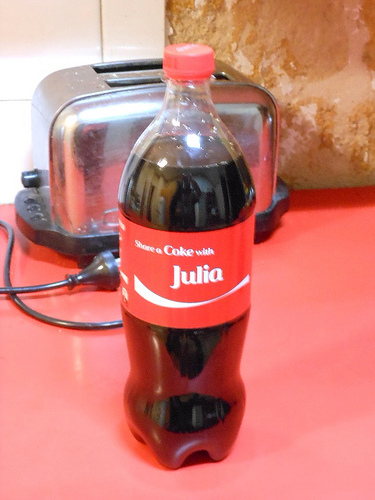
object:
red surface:
[0, 195, 375, 497]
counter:
[2, 191, 374, 497]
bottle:
[116, 44, 255, 469]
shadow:
[288, 188, 373, 209]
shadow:
[246, 332, 371, 452]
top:
[162, 41, 214, 84]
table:
[0, 193, 373, 500]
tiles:
[0, 0, 100, 100]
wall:
[0, 1, 374, 207]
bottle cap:
[162, 42, 215, 78]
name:
[169, 264, 223, 289]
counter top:
[0, 186, 375, 500]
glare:
[187, 133, 200, 149]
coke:
[116, 41, 256, 472]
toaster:
[21, 55, 278, 236]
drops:
[177, 144, 183, 150]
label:
[118, 212, 255, 331]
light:
[187, 133, 201, 147]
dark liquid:
[116, 153, 256, 229]